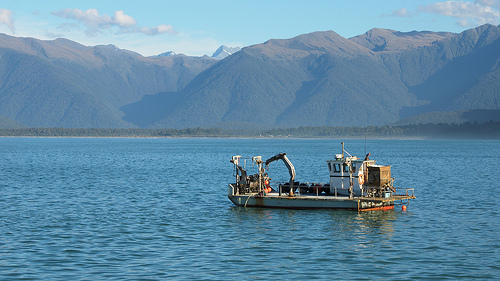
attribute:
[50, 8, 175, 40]
clouds — white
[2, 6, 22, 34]
clouds — white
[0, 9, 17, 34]
cloud — white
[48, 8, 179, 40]
cloud — white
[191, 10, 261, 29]
sky — blue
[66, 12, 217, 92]
clouds — white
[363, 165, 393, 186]
brown box — elevated, square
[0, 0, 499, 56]
clouds — white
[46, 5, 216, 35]
sky — baby blue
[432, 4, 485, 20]
clouds — white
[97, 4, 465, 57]
sky — blue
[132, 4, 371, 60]
sky — blue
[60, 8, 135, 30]
cloud — white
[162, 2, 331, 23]
sky — blue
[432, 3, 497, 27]
cloud — white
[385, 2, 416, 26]
cloud — white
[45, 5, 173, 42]
cloud — white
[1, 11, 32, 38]
cloud — white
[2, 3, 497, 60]
sky — blue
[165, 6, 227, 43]
sky — blue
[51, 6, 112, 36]
cloud — white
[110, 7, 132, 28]
cloud — white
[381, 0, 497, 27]
cloud — white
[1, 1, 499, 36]
clouds — white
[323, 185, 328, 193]
objects — round, black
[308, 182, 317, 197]
objects — round, black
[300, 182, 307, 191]
objects — round, black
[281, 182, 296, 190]
objects — round, black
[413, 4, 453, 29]
clouds — white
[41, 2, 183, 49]
clouds — white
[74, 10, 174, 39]
sky — blue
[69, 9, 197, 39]
cloud — white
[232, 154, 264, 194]
poles — gray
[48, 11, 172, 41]
clouds — floating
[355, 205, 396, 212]
stripe — orange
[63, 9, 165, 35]
clouds — white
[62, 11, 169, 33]
clouds — white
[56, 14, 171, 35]
clouds — white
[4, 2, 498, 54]
sky — blue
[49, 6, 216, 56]
clouds — white